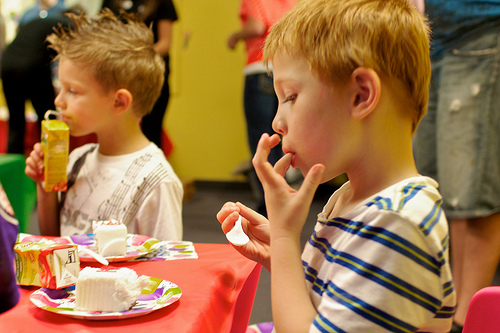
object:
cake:
[92, 219, 126, 256]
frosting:
[93, 220, 127, 255]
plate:
[62, 233, 161, 262]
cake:
[74, 267, 151, 313]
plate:
[26, 271, 182, 320]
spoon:
[223, 213, 250, 246]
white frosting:
[71, 266, 136, 311]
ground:
[427, 134, 459, 161]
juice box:
[13, 238, 81, 291]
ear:
[113, 88, 132, 115]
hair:
[262, 2, 430, 135]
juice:
[40, 119, 71, 192]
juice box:
[39, 119, 72, 193]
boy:
[24, 9, 184, 242]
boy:
[216, 0, 459, 333]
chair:
[462, 287, 499, 332]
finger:
[253, 134, 279, 186]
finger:
[221, 212, 239, 235]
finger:
[236, 202, 269, 225]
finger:
[215, 205, 236, 224]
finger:
[220, 202, 237, 210]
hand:
[252, 133, 326, 235]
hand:
[215, 201, 270, 268]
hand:
[24, 142, 52, 184]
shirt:
[297, 177, 458, 333]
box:
[41, 120, 70, 192]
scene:
[2, 4, 496, 325]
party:
[28, 15, 458, 320]